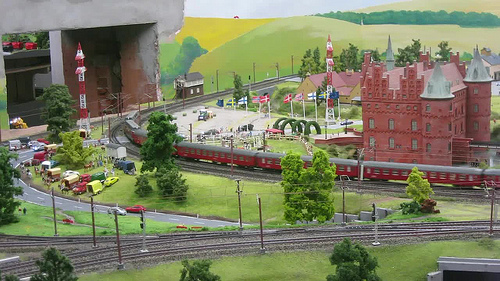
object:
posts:
[242, 99, 343, 125]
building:
[359, 42, 494, 175]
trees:
[134, 113, 188, 205]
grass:
[189, 183, 222, 211]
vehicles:
[39, 160, 123, 197]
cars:
[105, 198, 147, 217]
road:
[52, 197, 217, 229]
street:
[157, 211, 230, 227]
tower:
[60, 45, 105, 120]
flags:
[229, 89, 355, 116]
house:
[172, 67, 208, 98]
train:
[185, 147, 499, 196]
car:
[81, 174, 132, 197]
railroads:
[144, 219, 497, 264]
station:
[361, 81, 456, 169]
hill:
[112, 180, 197, 206]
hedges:
[277, 116, 336, 147]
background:
[277, 3, 499, 57]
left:
[4, 17, 172, 205]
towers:
[355, 37, 490, 99]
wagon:
[115, 157, 136, 174]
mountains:
[200, 5, 483, 45]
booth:
[173, 63, 231, 112]